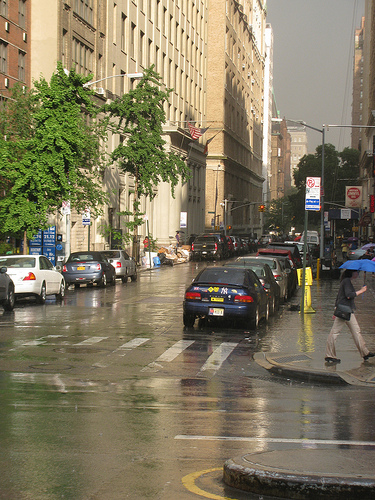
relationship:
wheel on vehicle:
[58, 277, 66, 298] [7, 237, 75, 306]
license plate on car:
[208, 307, 224, 316] [183, 267, 271, 329]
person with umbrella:
[325, 269, 375, 363] [332, 255, 373, 275]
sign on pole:
[305, 176, 321, 212] [299, 209, 309, 313]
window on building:
[224, 22, 228, 54] [206, 3, 263, 223]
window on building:
[173, 22, 177, 55] [109, 2, 205, 226]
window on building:
[127, 23, 136, 59] [43, 0, 108, 243]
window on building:
[72, 40, 76, 60] [6, 4, 41, 155]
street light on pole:
[122, 67, 148, 81] [317, 129, 328, 309]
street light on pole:
[250, 198, 267, 209] [317, 129, 328, 309]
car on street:
[183, 267, 271, 329] [5, 247, 362, 496]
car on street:
[208, 227, 314, 315] [5, 247, 362, 496]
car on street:
[62, 252, 116, 285] [138, 270, 183, 327]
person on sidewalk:
[333, 264, 363, 312] [312, 277, 330, 332]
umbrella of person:
[344, 255, 374, 271] [324, 269, 362, 361]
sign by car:
[299, 264, 319, 318] [221, 261, 283, 314]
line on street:
[196, 340, 239, 377] [3, 266, 373, 402]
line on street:
[138, 338, 195, 372] [3, 266, 373, 402]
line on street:
[92, 335, 152, 367] [3, 266, 373, 402]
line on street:
[72, 334, 109, 346] [3, 266, 373, 402]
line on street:
[7, 331, 64, 351] [3, 266, 373, 402]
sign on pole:
[305, 176, 321, 212] [317, 126, 328, 259]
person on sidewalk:
[325, 269, 375, 363] [261, 239, 374, 383]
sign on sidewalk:
[296, 266, 315, 314] [280, 277, 374, 370]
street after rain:
[3, 266, 373, 402] [75, 295, 109, 312]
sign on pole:
[305, 176, 320, 209] [298, 210, 307, 318]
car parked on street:
[184, 266, 276, 334] [3, 266, 373, 402]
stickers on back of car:
[192, 286, 243, 292] [182, 266, 270, 328]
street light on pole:
[271, 113, 322, 141] [318, 128, 326, 279]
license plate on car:
[205, 304, 228, 320] [181, 264, 267, 337]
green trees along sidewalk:
[5, 61, 194, 270] [137, 255, 156, 271]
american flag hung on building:
[177, 117, 210, 152] [6, 0, 274, 230]